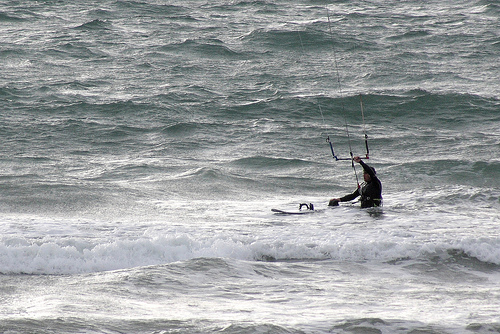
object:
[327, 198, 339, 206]
handle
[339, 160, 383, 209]
wetsuit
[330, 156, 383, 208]
person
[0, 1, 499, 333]
day time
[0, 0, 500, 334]
water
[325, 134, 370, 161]
kite handle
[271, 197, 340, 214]
board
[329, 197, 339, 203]
hand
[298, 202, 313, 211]
foot strap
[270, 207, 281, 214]
edge